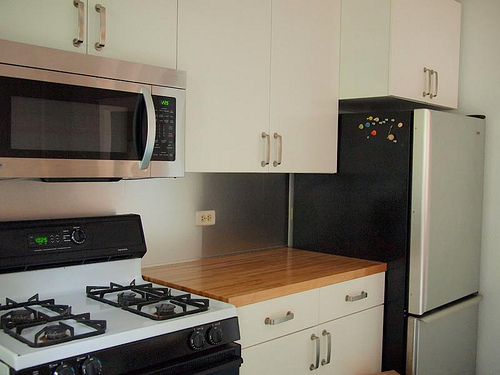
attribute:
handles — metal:
[68, 1, 115, 52]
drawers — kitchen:
[248, 290, 386, 338]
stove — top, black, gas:
[19, 278, 204, 332]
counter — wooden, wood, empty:
[347, 250, 396, 274]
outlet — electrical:
[180, 204, 236, 226]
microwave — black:
[7, 90, 179, 177]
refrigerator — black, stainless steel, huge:
[411, 122, 474, 288]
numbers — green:
[157, 98, 172, 108]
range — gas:
[66, 232, 95, 250]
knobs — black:
[184, 327, 228, 346]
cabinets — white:
[256, 305, 370, 355]